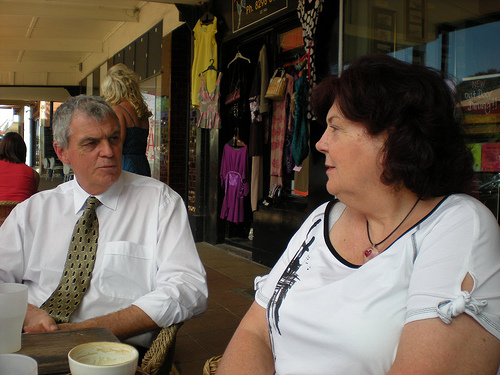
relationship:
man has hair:
[1, 97, 209, 358] [50, 99, 119, 148]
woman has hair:
[103, 65, 151, 176] [102, 64, 147, 119]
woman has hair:
[211, 55, 499, 372] [310, 54, 474, 198]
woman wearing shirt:
[211, 55, 499, 372] [253, 199, 498, 373]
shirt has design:
[253, 199, 498, 373] [264, 212, 322, 367]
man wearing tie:
[1, 97, 209, 358] [42, 197, 101, 326]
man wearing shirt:
[1, 97, 209, 358] [0, 174, 208, 362]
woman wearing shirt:
[0, 131, 40, 201] [0, 164, 33, 202]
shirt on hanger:
[218, 144, 248, 224] [228, 126, 245, 149]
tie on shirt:
[42, 197, 101, 326] [0, 174, 208, 362]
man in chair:
[1, 97, 209, 358] [139, 327, 182, 373]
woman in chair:
[211, 55, 499, 372] [204, 354, 228, 374]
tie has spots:
[42, 197, 101, 326] [80, 245, 87, 252]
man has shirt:
[1, 97, 209, 358] [0, 174, 208, 362]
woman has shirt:
[0, 131, 40, 201] [0, 164, 33, 202]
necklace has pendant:
[364, 190, 426, 242] [361, 246, 376, 260]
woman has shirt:
[211, 55, 499, 372] [253, 199, 498, 373]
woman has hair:
[0, 131, 40, 201] [0, 133, 28, 165]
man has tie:
[1, 97, 209, 358] [42, 197, 101, 326]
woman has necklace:
[211, 55, 499, 372] [364, 190, 426, 242]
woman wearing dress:
[103, 65, 151, 176] [121, 101, 150, 174]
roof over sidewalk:
[0, 0, 163, 87] [175, 242, 272, 373]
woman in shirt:
[211, 55, 499, 372] [253, 199, 498, 373]